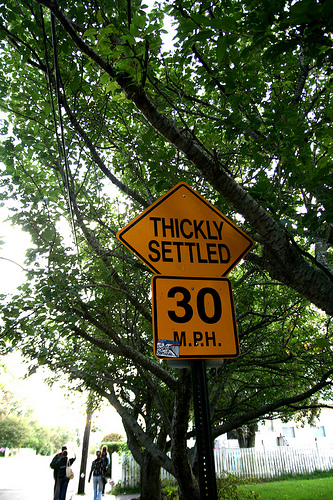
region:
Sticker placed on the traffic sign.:
[152, 332, 183, 361]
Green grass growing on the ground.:
[271, 479, 331, 498]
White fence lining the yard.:
[232, 442, 329, 475]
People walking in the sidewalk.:
[91, 442, 114, 498]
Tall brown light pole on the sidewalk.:
[77, 410, 90, 496]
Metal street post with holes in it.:
[186, 369, 235, 498]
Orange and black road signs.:
[116, 177, 251, 366]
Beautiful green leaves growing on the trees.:
[11, 2, 332, 164]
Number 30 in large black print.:
[162, 280, 228, 326]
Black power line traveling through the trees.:
[40, 23, 82, 257]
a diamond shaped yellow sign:
[117, 183, 260, 283]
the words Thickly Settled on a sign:
[147, 210, 232, 274]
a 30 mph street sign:
[144, 275, 243, 363]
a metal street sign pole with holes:
[191, 366, 218, 495]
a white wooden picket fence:
[234, 443, 318, 476]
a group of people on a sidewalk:
[53, 440, 115, 496]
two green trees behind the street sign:
[49, 261, 149, 413]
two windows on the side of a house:
[279, 421, 327, 441]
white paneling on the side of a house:
[293, 439, 307, 444]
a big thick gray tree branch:
[274, 238, 328, 318]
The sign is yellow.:
[108, 180, 256, 372]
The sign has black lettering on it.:
[121, 212, 244, 368]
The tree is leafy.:
[29, 183, 145, 397]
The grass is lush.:
[246, 478, 321, 499]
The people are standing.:
[27, 444, 137, 489]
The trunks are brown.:
[117, 364, 206, 499]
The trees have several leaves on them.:
[44, 27, 327, 168]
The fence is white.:
[214, 435, 331, 480]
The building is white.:
[203, 407, 331, 470]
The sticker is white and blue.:
[149, 335, 182, 367]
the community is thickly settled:
[132, 197, 264, 347]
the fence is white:
[231, 443, 321, 475]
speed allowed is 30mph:
[152, 291, 242, 357]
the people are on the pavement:
[52, 446, 119, 495]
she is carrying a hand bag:
[51, 454, 81, 487]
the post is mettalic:
[188, 396, 227, 492]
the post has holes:
[190, 396, 218, 498]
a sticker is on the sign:
[155, 338, 177, 364]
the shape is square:
[115, 276, 149, 493]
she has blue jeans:
[90, 479, 109, 498]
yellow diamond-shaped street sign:
[114, 177, 256, 276]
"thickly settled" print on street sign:
[145, 210, 232, 268]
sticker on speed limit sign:
[155, 336, 180, 359]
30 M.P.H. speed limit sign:
[151, 275, 237, 358]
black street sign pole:
[186, 359, 220, 498]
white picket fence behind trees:
[117, 436, 331, 487]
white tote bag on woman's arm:
[63, 456, 76, 482]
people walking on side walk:
[46, 442, 114, 498]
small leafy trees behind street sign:
[2, 190, 329, 498]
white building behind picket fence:
[174, 394, 332, 448]